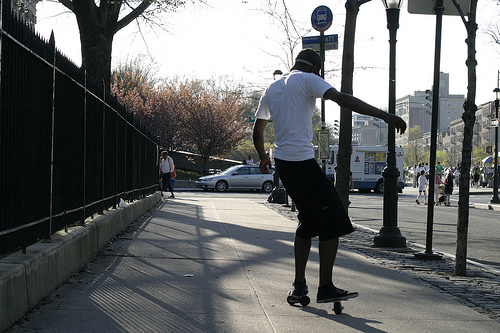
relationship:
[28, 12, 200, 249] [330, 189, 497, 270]
fence by side of street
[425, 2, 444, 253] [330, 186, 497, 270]
poles on side of street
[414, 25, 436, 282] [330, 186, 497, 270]
poles on side of street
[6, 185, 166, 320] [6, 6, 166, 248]
base near fence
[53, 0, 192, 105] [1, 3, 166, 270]
tree behind fence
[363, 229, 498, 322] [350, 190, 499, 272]
cobblestone on street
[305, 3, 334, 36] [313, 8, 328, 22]
sign on bus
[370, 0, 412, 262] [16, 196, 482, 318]
lamp on sidewalk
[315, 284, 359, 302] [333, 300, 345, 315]
shoes with wheels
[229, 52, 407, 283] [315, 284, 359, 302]
man wearing shoes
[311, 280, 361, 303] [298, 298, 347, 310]
shoes with wheels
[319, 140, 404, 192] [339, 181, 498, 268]
truck parked on side of road